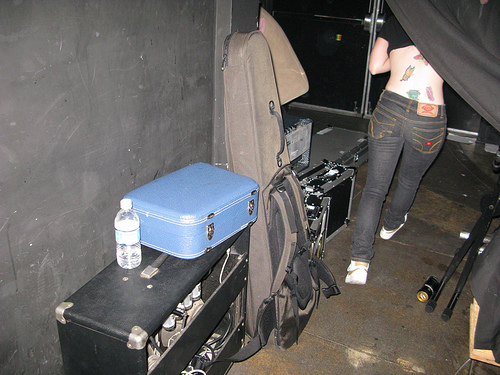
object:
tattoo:
[413, 53, 431, 66]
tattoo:
[400, 65, 416, 83]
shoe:
[344, 260, 371, 285]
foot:
[345, 259, 372, 285]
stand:
[423, 187, 500, 320]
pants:
[347, 86, 450, 265]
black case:
[54, 226, 250, 375]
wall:
[0, 2, 258, 374]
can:
[417, 276, 441, 303]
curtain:
[383, 0, 498, 132]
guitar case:
[218, 31, 335, 364]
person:
[340, 9, 449, 285]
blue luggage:
[118, 161, 260, 260]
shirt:
[373, 23, 418, 57]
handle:
[267, 100, 287, 166]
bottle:
[114, 198, 143, 269]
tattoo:
[426, 86, 435, 100]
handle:
[141, 253, 170, 278]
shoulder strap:
[269, 192, 297, 295]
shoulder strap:
[283, 174, 310, 249]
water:
[114, 210, 143, 267]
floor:
[220, 104, 495, 373]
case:
[293, 160, 358, 243]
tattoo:
[407, 88, 421, 100]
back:
[370, 24, 449, 109]